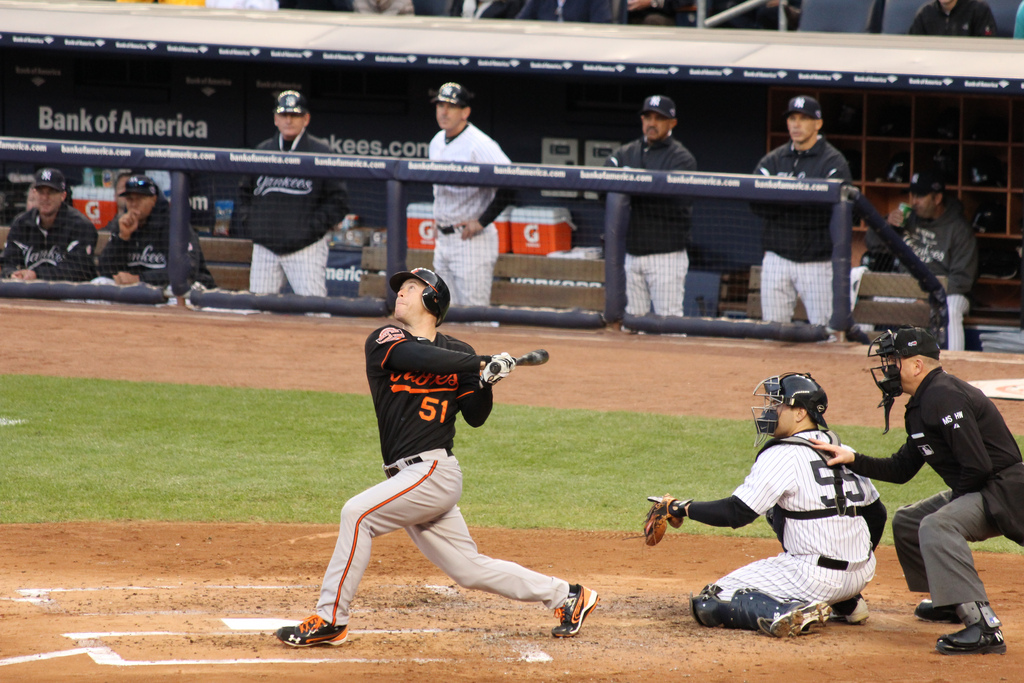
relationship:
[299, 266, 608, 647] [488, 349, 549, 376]
baseball player holding baseball bat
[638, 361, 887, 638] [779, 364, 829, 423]
catcher wearing helmet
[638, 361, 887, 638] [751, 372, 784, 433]
catcher wearing face mask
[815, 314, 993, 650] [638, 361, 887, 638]
man is touching the catcher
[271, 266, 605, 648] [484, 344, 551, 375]
baseball player swinging baseball bat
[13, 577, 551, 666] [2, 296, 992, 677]
box painted on ground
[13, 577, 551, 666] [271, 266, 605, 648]
box guiding baseball player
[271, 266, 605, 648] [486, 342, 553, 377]
baseball player holding bat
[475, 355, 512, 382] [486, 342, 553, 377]
hand holding bat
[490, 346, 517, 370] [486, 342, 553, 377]
hand holding bat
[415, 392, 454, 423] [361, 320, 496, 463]
number 51 printed on uniform shirt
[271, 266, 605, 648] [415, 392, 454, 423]
baseball player wearing number 51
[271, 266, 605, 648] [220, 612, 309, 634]
baseball player standing next to home plate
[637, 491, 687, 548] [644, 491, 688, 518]
glove worn on hand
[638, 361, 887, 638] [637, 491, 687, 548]
catcher wearing glove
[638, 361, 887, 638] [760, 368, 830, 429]
catcher wearing helmet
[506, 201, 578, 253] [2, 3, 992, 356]
cooler sitting inside dugout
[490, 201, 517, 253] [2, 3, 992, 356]
cooler sitting inside dugout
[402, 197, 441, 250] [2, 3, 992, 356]
cooler sitting inside dugout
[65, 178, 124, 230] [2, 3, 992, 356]
cooler sitting inside dugout